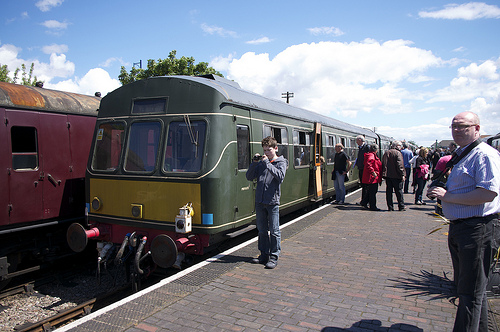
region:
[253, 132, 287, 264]
boy taking picture with phone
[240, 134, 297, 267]
boy with gray sweater and jeans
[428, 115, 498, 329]
balding man with glasses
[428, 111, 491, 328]
man wearing blue shirt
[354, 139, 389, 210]
person wearing red sweater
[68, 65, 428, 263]
yellow and green train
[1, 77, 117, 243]
red and black train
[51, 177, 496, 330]
red and black brick platform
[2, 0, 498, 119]
blue sky with white clouds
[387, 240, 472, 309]
shadow of potted plant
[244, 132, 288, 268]
Boy holding a camera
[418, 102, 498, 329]
Man wearing glasses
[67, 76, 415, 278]
Green train on tracks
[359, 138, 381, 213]
Woman with red jacket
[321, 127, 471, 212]
People getting on the train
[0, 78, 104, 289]
Red train with rusted ceiling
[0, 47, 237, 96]
Trains behind the trains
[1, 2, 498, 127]
Blue sky with white clouds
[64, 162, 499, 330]
platform made of bricks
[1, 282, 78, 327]
Gravels between the tracks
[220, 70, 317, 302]
Boy holding a camera.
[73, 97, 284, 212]
Windows on the train.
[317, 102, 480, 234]
People waiting for the train.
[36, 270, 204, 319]
Rails under the train.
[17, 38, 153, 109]
Clouds in the sky.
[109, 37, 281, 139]
Tree behind the train.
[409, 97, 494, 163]
Man with glasses on.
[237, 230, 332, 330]
Bricks on the road.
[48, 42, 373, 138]
Blue sky with clouds.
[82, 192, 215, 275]
Lights on the train.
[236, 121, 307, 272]
child with a grey sweater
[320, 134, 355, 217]
Person in a black shirt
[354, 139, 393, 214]
Person in a red coat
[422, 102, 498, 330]
Person wearing glasses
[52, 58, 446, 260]
Green train at the station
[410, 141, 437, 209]
Person in a black shirt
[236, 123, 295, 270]
Child taking a photo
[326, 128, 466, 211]
Group of people at a train station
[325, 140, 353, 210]
Person boarding a train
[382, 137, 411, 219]
Person in a brown coat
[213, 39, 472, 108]
fluffy white clouds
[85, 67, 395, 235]
army green train with yellow front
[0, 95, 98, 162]
rust spot on red train roof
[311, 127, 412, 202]
people boarding a train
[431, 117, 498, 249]
bald man wearing glasses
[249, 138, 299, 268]
boy taking a picture with camera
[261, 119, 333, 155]
open windows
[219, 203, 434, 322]
brick walkway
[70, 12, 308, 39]
bright blue sky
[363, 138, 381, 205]
heavyset person in red sweatshirt